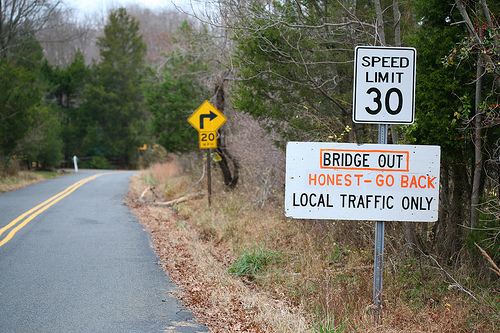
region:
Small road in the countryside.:
[3, 156, 193, 331]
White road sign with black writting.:
[350, 42, 415, 122]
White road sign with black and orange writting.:
[283, 140, 438, 218]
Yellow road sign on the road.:
[185, 95, 230, 152]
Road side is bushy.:
[150, 130, 477, 321]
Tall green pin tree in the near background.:
[66, 5, 164, 170]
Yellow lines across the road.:
[3, 167, 110, 237]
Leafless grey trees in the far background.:
[48, 3, 184, 49]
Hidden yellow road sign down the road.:
[130, 136, 147, 152]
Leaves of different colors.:
[443, 14, 498, 145]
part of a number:
[370, 73, 415, 123]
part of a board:
[361, 155, 386, 180]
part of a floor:
[48, 210, 120, 312]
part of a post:
[366, 226, 395, 266]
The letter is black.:
[358, 51, 371, 70]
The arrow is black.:
[193, 107, 220, 131]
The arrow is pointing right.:
[196, 108, 218, 130]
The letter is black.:
[368, 54, 380, 69]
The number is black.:
[363, 83, 385, 119]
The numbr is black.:
[381, 83, 405, 116]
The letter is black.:
[398, 53, 410, 72]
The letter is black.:
[361, 69, 375, 84]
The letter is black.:
[394, 70, 406, 85]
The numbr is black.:
[199, 130, 208, 144]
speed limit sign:
[349, 45, 414, 125]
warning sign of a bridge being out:
[280, 139, 439, 222]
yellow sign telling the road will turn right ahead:
[190, 95, 227, 133]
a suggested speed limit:
[198, 128, 216, 150]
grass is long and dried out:
[134, 146, 485, 331]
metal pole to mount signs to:
[369, 118, 389, 300]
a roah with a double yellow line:
[2, 164, 149, 331]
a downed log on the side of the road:
[138, 190, 224, 208]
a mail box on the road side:
[66, 153, 82, 175]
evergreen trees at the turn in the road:
[79, 16, 206, 173]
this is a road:
[45, 175, 119, 285]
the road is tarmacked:
[18, 190, 113, 295]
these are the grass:
[245, 140, 273, 263]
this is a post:
[185, 97, 227, 210]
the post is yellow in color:
[190, 98, 227, 149]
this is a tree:
[75, 23, 138, 141]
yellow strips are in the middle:
[40, 183, 72, 208]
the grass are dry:
[241, 148, 266, 240]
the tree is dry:
[328, 7, 401, 45]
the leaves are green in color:
[415, 30, 447, 92]